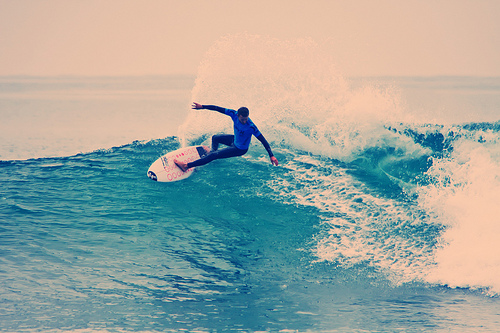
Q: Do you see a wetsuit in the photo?
A: Yes, there is a wetsuit.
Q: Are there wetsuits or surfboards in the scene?
A: Yes, there is a wetsuit.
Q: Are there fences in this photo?
A: No, there are no fences.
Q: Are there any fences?
A: No, there are no fences.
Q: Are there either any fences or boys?
A: No, there are no fences or boys.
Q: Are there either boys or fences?
A: No, there are no fences or boys.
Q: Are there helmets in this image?
A: No, there are no helmets.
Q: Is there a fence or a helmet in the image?
A: No, there are no helmets or fences.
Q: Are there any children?
A: No, there are no children.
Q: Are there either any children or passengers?
A: No, there are no children or passengers.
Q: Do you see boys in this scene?
A: No, there are no boys.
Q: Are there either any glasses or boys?
A: No, there are no boys or glasses.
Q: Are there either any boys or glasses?
A: No, there are no boys or glasses.